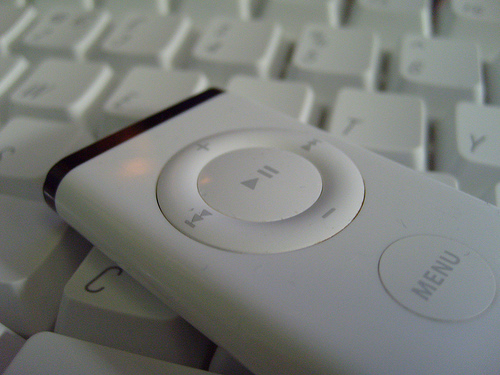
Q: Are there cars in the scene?
A: No, there are no cars.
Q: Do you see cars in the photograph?
A: No, there are no cars.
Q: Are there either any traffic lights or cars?
A: No, there are no cars or traffic lights.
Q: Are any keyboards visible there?
A: Yes, there is a keyboard.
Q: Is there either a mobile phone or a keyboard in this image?
A: Yes, there is a keyboard.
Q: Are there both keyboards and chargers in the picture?
A: No, there is a keyboard but no chargers.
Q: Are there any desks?
A: No, there are no desks.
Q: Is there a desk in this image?
A: No, there are no desks.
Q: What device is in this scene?
A: The device is a keyboard.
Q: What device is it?
A: The device is a keyboard.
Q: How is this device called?
A: This is a keyboard.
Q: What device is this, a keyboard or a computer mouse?
A: This is a keyboard.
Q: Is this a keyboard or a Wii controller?
A: This is a keyboard.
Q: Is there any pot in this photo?
A: No, there are no pots.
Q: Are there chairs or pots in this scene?
A: No, there are no pots or chairs.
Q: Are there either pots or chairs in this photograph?
A: No, there are no pots or chairs.